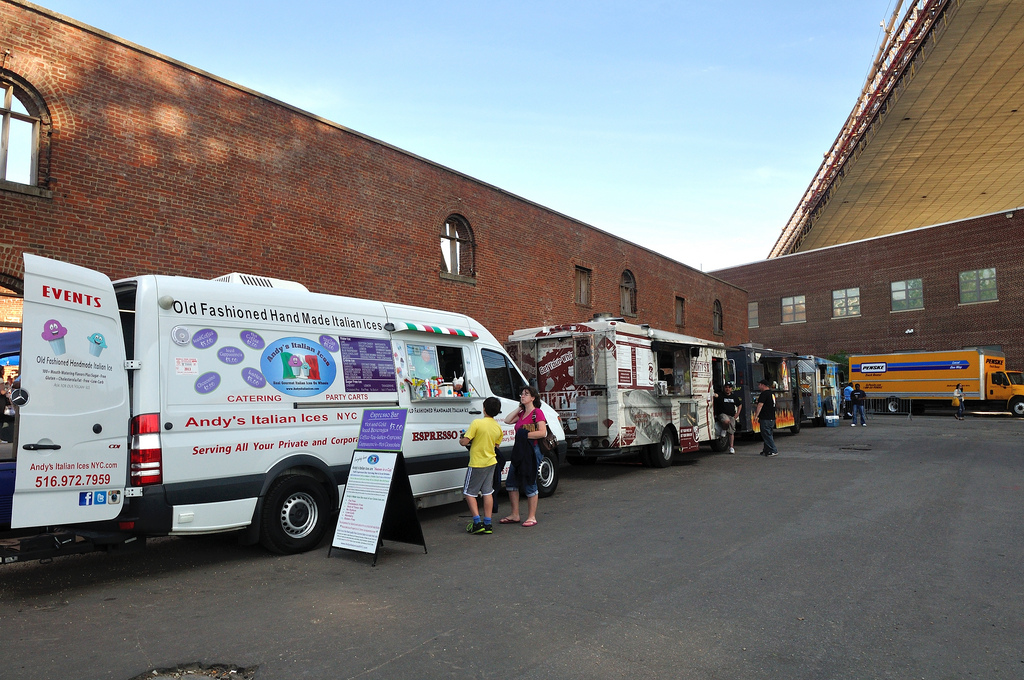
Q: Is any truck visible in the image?
A: Yes, there is a truck.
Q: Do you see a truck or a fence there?
A: Yes, there is a truck.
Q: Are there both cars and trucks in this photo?
A: No, there is a truck but no cars.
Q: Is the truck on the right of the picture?
A: Yes, the truck is on the right of the image.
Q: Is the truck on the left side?
A: No, the truck is on the right of the image.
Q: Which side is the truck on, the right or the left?
A: The truck is on the right of the image.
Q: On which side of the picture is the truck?
A: The truck is on the right of the image.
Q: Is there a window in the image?
A: Yes, there is a window.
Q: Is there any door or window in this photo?
A: Yes, there is a window.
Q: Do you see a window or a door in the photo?
A: Yes, there is a window.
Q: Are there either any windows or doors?
A: Yes, there is a window.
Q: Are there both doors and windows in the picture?
A: Yes, there are both a window and a door.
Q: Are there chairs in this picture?
A: No, there are no chairs.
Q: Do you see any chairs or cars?
A: No, there are no chairs or cars.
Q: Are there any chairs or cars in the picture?
A: No, there are no chairs or cars.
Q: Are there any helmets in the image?
A: No, there are no helmets.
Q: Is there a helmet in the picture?
A: No, there are no helmets.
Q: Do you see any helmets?
A: No, there are no helmets.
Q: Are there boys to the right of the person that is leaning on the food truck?
A: Yes, there is a boy to the right of the person.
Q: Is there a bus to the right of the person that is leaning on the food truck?
A: No, there is a boy to the right of the person.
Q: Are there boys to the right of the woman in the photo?
A: Yes, there is a boy to the right of the woman.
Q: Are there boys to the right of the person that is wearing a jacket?
A: Yes, there is a boy to the right of the woman.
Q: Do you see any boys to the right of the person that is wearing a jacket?
A: Yes, there is a boy to the right of the woman.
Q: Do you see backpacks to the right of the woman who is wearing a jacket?
A: No, there is a boy to the right of the woman.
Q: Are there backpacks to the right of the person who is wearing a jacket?
A: No, there is a boy to the right of the woman.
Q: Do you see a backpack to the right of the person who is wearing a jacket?
A: No, there is a boy to the right of the woman.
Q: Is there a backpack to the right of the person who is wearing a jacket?
A: No, there is a boy to the right of the woman.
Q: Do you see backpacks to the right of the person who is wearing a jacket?
A: No, there is a boy to the right of the woman.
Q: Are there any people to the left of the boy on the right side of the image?
A: Yes, there is a person to the left of the boy.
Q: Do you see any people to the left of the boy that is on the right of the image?
A: Yes, there is a person to the left of the boy.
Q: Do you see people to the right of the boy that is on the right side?
A: No, the person is to the left of the boy.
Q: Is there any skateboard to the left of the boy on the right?
A: No, there is a person to the left of the boy.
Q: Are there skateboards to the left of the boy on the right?
A: No, there is a person to the left of the boy.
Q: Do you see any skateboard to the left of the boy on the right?
A: No, there is a person to the left of the boy.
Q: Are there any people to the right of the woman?
A: Yes, there is a person to the right of the woman.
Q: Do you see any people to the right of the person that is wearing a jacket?
A: Yes, there is a person to the right of the woman.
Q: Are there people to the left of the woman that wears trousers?
A: No, the person is to the right of the woman.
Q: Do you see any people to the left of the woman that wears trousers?
A: No, the person is to the right of the woman.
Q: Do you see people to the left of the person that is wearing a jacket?
A: No, the person is to the right of the woman.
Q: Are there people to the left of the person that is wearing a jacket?
A: No, the person is to the right of the woman.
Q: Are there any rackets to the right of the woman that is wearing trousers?
A: No, there is a person to the right of the woman.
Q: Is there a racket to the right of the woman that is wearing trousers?
A: No, there is a person to the right of the woman.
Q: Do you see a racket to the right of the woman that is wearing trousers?
A: No, there is a person to the right of the woman.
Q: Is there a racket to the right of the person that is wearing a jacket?
A: No, there is a person to the right of the woman.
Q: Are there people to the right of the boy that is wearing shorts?
A: Yes, there is a person to the right of the boy.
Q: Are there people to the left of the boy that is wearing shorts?
A: No, the person is to the right of the boy.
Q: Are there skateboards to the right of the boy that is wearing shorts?
A: No, there is a person to the right of the boy.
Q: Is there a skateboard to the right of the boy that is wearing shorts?
A: No, there is a person to the right of the boy.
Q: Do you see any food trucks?
A: Yes, there is a food truck.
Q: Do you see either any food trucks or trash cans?
A: Yes, there is a food truck.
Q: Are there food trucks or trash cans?
A: Yes, there is a food truck.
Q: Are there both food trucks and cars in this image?
A: No, there is a food truck but no cars.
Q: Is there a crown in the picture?
A: No, there are no crowns.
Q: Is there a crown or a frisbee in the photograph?
A: No, there are no crowns or frisbees.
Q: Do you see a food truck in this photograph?
A: Yes, there is a food truck.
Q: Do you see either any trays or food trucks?
A: Yes, there is a food truck.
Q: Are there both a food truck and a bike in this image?
A: No, there is a food truck but no bikes.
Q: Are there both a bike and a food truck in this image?
A: No, there is a food truck but no bikes.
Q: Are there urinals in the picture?
A: No, there are no urinals.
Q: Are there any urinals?
A: No, there are no urinals.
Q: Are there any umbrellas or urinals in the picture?
A: No, there are no urinals or umbrellas.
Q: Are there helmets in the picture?
A: No, there are no helmets.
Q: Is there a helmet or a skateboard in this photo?
A: No, there are no helmets or skateboards.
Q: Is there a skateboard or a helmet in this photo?
A: No, there are no helmets or skateboards.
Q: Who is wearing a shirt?
A: The boy is wearing a shirt.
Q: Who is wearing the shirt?
A: The boy is wearing a shirt.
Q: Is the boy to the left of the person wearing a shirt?
A: Yes, the boy is wearing a shirt.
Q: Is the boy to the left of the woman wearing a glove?
A: No, the boy is wearing a shirt.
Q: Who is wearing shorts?
A: The boy is wearing shorts.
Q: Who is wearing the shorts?
A: The boy is wearing shorts.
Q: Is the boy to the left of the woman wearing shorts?
A: Yes, the boy is wearing shorts.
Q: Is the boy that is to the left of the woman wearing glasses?
A: No, the boy is wearing shorts.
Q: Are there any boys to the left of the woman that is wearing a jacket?
A: Yes, there is a boy to the left of the woman.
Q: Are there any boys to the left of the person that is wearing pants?
A: Yes, there is a boy to the left of the woman.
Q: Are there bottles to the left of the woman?
A: No, there is a boy to the left of the woman.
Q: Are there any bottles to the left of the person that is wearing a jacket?
A: No, there is a boy to the left of the woman.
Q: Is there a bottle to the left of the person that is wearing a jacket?
A: No, there is a boy to the left of the woman.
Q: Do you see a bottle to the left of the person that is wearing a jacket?
A: No, there is a boy to the left of the woman.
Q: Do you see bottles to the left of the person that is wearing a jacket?
A: No, there is a boy to the left of the woman.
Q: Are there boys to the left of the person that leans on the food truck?
A: Yes, there is a boy to the left of the person.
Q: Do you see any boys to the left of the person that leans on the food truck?
A: Yes, there is a boy to the left of the person.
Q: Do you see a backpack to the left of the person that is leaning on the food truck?
A: No, there is a boy to the left of the person.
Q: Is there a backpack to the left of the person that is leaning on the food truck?
A: No, there is a boy to the left of the person.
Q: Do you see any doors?
A: Yes, there is a door.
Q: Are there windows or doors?
A: Yes, there is a door.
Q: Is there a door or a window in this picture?
A: Yes, there is a door.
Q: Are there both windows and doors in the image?
A: Yes, there are both a door and a window.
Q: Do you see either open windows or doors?
A: Yes, there is an open door.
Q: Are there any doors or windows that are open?
A: Yes, the door is open.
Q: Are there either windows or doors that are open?
A: Yes, the door is open.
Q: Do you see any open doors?
A: Yes, there is an open door.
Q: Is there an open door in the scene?
A: Yes, there is an open door.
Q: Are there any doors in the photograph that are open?
A: Yes, there is a door that is open.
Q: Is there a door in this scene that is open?
A: Yes, there is a door that is open.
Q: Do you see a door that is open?
A: Yes, there is a door that is open.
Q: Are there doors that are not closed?
A: Yes, there is a open door.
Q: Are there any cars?
A: No, there are no cars.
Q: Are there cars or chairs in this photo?
A: No, there are no cars or chairs.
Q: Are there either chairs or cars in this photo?
A: No, there are no cars or chairs.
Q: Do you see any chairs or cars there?
A: No, there are no cars or chairs.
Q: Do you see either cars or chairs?
A: No, there are no cars or chairs.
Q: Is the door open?
A: Yes, the door is open.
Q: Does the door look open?
A: Yes, the door is open.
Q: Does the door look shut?
A: No, the door is open.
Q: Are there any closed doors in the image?
A: No, there is a door but it is open.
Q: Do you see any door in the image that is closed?
A: No, there is a door but it is open.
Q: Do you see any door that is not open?
A: No, there is a door but it is open.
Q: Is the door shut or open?
A: The door is open.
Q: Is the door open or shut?
A: The door is open.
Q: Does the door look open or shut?
A: The door is open.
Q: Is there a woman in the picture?
A: Yes, there is a woman.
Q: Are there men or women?
A: Yes, there is a woman.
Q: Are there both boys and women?
A: Yes, there are both a woman and a boy.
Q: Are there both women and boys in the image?
A: Yes, there are both a woman and a boy.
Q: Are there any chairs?
A: No, there are no chairs.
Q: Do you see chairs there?
A: No, there are no chairs.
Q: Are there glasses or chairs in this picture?
A: No, there are no chairs or glasses.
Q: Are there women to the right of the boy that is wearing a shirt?
A: Yes, there is a woman to the right of the boy.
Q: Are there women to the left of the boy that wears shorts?
A: No, the woman is to the right of the boy.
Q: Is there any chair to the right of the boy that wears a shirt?
A: No, there is a woman to the right of the boy.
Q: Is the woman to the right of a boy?
A: Yes, the woman is to the right of a boy.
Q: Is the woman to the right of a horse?
A: No, the woman is to the right of a boy.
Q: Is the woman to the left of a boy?
A: No, the woman is to the right of a boy.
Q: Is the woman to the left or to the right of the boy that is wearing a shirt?
A: The woman is to the right of the boy.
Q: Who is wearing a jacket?
A: The woman is wearing a jacket.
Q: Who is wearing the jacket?
A: The woman is wearing a jacket.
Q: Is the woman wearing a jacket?
A: Yes, the woman is wearing a jacket.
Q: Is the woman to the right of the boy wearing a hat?
A: No, the woman is wearing a jacket.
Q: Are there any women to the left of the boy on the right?
A: Yes, there is a woman to the left of the boy.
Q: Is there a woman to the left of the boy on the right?
A: Yes, there is a woman to the left of the boy.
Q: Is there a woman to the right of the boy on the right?
A: No, the woman is to the left of the boy.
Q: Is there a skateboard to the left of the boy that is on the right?
A: No, there is a woman to the left of the boy.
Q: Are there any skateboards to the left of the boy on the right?
A: No, there is a woman to the left of the boy.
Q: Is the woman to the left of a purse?
A: No, the woman is to the left of a boy.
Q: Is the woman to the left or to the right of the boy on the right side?
A: The woman is to the left of the boy.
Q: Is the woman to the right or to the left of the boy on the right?
A: The woman is to the left of the boy.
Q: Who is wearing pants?
A: The woman is wearing pants.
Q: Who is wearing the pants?
A: The woman is wearing pants.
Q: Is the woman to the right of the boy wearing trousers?
A: Yes, the woman is wearing trousers.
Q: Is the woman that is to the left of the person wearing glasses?
A: No, the woman is wearing trousers.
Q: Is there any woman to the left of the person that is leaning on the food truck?
A: Yes, there is a woman to the left of the person.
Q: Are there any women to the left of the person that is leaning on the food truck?
A: Yes, there is a woman to the left of the person.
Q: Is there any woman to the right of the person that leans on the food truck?
A: No, the woman is to the left of the person.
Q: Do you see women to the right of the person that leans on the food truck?
A: No, the woman is to the left of the person.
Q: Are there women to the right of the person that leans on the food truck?
A: No, the woman is to the left of the person.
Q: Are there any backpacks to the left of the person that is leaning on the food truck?
A: No, there is a woman to the left of the person.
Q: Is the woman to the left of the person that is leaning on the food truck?
A: Yes, the woman is to the left of the person.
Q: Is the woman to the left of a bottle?
A: No, the woman is to the left of the person.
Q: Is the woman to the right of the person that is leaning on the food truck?
A: No, the woman is to the left of the person.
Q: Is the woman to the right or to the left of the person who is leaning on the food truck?
A: The woman is to the left of the person.